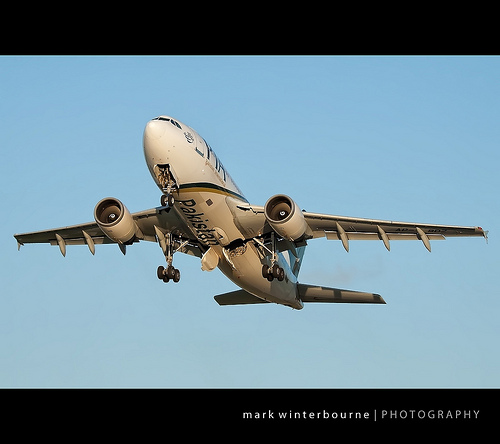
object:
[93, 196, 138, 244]
engine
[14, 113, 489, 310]
plane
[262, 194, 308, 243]
engine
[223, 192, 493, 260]
wing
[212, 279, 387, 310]
tail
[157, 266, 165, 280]
wheels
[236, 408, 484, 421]
name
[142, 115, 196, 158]
cockpit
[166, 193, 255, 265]
belly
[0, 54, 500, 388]
sky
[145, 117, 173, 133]
nose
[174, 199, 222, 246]
name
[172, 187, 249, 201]
stripes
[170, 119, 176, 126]
window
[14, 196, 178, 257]
wing